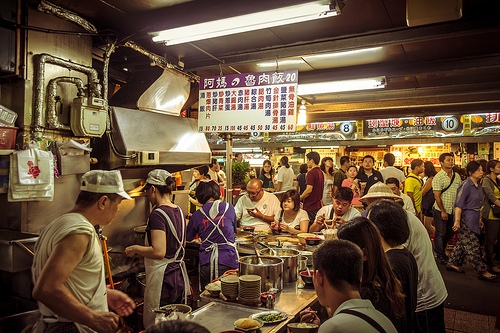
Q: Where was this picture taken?
A: Restaurant.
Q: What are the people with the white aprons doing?
A: Cooking.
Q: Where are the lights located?
A: Suspended from ceiling.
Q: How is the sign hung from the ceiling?
A: With chains.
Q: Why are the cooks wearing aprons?
A: To keep their clothes clean.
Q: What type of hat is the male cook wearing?
A: White baseball hat.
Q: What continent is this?
A: Asia.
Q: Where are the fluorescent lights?
A: Ceiling.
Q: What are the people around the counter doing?
A: Eating.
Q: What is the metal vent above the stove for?
A: Venting smoke.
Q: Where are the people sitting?
A: Counter.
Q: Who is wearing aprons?
A: The workers.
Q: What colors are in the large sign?
A: Red, white and blue.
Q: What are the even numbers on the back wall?
A: 6, 8 and 10.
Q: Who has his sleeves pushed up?
A: The closest cook.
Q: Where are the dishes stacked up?
A: On the counter.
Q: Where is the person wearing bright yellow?
A: Walking in the crowd.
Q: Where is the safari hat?
A: At the end of the counter.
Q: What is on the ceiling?
A: Bright lights.